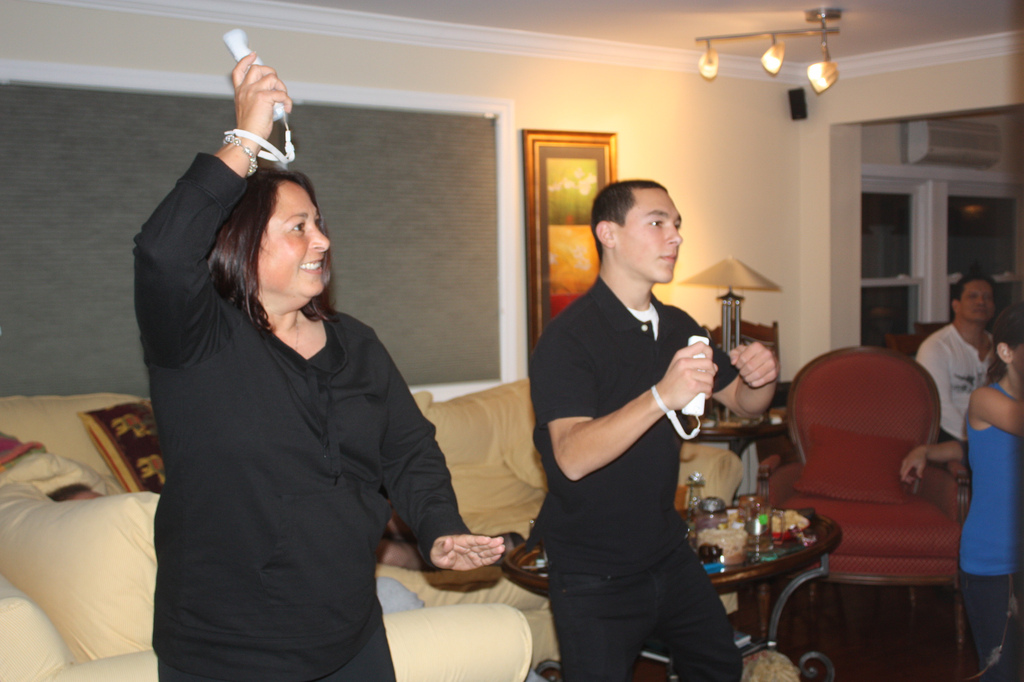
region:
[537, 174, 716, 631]
boy holding a wii remote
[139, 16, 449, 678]
woman with wii remote in the air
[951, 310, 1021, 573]
child wearing a blue shirt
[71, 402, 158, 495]
pillow on the couch behind the woman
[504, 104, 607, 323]
picture on the wall behind the boy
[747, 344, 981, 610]
red chair in the corner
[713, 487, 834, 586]
coffee table full of things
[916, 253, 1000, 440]
man is watching the people play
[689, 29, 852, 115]
lights in the ceiling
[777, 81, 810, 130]
small black surround sound speaker in the corner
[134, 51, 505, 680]
woman in black holding controller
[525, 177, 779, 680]
man in black holding controller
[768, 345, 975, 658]
red upholstered armchair near corner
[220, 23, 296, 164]
Wii controller in woman's right hand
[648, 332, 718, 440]
Wii controller in man's right hand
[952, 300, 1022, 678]
woman in blue tank top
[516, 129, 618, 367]
painting hanging on back wall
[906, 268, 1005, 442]
man wearing white shirt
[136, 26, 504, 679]
woman in black playing Wii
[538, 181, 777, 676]
guy in black playing Wii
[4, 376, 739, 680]
beige sectional couch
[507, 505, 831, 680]
small coffee table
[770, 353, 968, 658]
a red chair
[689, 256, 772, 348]
small table lamp in the corner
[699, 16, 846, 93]
lights hanging from ceiling lighting a piece of art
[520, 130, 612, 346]
framed piece of art on the wall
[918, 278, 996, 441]
man in a white t-shirt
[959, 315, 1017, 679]
female in a blue shirt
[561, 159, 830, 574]
a man playing the wii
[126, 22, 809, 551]
the people are standing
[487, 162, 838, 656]
this is a man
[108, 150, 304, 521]
the woman has her arm up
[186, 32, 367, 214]
this is a controller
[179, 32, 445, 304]
the controller is white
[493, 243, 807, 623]
the boy has his fists up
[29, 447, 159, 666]
the couch is tan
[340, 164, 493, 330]
the back wall is gray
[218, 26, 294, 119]
a Wii video game controller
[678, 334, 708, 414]
a Wii video game controller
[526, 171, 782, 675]
a man playing a video game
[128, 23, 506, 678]
a woman playing a video game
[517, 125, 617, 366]
a framed painting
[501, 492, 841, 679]
an oval coffee table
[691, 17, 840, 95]
overhead track lighting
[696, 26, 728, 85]
light fixture on ceiling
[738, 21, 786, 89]
light fixture on ceiling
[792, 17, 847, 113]
light fixture on ceiling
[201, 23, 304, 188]
white wiimote controller in hand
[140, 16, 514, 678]
woman wearing all black playing wii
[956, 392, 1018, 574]
blue colored shirt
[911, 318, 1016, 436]
white colored shirt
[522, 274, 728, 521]
black colored shirt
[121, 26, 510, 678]
Woman wearing all black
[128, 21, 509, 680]
Woman playing motion controlled game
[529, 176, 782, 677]
Man playing motion controlled game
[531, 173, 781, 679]
man wearing all black